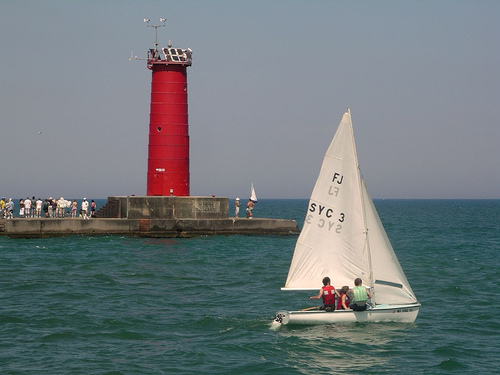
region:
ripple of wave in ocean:
[181, 304, 223, 324]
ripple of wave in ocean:
[98, 322, 145, 346]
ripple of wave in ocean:
[439, 355, 464, 374]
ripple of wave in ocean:
[446, 310, 467, 332]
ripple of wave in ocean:
[109, 326, 134, 342]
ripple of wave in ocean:
[148, 348, 175, 368]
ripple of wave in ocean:
[131, 274, 172, 293]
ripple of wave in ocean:
[36, 278, 84, 305]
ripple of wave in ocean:
[187, 252, 217, 274]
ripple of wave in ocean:
[230, 250, 257, 277]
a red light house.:
[136, 40, 209, 216]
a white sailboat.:
[261, 88, 441, 338]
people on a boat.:
[312, 260, 381, 317]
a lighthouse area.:
[0, 179, 332, 267]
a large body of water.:
[0, 198, 495, 372]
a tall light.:
[134, 6, 171, 58]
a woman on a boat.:
[313, 272, 342, 312]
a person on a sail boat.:
[346, 270, 368, 312]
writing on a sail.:
[305, 198, 354, 236]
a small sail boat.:
[235, 178, 261, 224]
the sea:
[104, 239, 214, 374]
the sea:
[132, 270, 228, 368]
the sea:
[105, 333, 220, 371]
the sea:
[143, 254, 276, 359]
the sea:
[187, 308, 234, 357]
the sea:
[156, 297, 211, 369]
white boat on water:
[295, 111, 446, 349]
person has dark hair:
[315, 281, 334, 298]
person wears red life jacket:
[318, 283, 333, 305]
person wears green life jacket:
[346, 281, 383, 309]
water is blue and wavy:
[89, 256, 270, 358]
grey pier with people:
[23, 195, 268, 225]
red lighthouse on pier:
[130, 33, 205, 194]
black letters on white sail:
[297, 155, 337, 240]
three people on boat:
[314, 270, 382, 301]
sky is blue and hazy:
[37, 29, 109, 159]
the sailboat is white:
[285, 92, 390, 371]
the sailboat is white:
[274, 184, 359, 361]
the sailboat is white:
[311, 180, 401, 370]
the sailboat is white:
[309, 77, 492, 367]